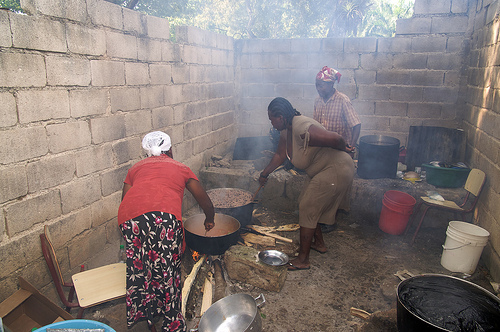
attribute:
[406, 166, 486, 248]
chair — brown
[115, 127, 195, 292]
lady — pictured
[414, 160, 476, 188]
tub — green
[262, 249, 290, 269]
plate — pictured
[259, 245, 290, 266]
silver pan — round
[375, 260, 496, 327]
pot — black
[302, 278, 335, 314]
ground — pictured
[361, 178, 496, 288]
buckets — pictured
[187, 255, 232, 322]
logs — burning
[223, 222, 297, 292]
logs — burning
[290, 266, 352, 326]
ground — pictured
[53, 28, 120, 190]
wall — pictured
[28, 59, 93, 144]
cement blocks — gray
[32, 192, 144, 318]
chair — pictured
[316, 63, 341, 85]
head scarf — red and white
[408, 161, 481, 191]
trough — green 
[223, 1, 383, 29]
tree — pictured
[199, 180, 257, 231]
pot — large, big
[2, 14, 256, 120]
wall — pictured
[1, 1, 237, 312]
wall — stained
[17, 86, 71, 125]
cinder block — stained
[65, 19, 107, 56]
cinder block — stained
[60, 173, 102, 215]
cinder block — stained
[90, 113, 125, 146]
cinder block — stained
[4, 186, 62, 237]
cinder block — stained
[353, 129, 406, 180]
stock pot — tall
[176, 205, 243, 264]
pot — big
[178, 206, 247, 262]
pot — large, black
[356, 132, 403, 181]
pot — black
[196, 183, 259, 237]
pot — black